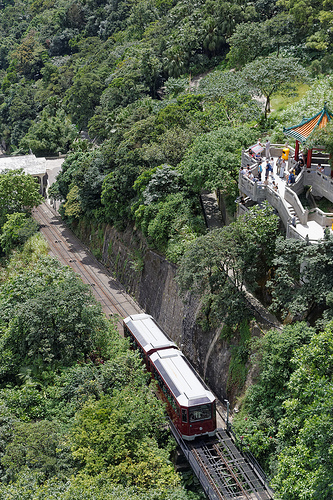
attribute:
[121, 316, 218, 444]
train — red, metal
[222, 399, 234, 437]
pole — white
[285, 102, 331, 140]
roof — brown, orange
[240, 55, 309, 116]
tree — green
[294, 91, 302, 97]
leaf — green, big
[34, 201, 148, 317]
track — metal, metallic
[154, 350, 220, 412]
top — silver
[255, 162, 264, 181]
person — looking, standing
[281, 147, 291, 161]
jacket — yellow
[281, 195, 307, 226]
steps — concrete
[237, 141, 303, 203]
platform — asian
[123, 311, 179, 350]
roof — white